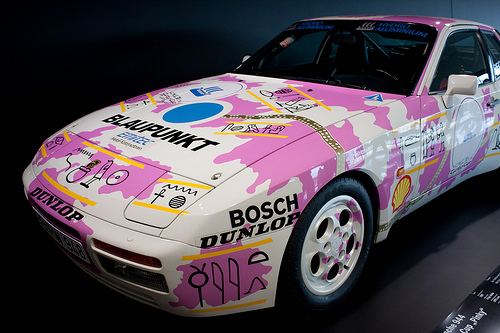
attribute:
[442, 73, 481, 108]
car mirror — white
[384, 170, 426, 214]
logo — Shell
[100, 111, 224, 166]
"blaupunkt" — black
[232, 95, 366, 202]
paint — Pink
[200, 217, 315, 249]
dunlop — black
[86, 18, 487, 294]
car — pink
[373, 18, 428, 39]
writing — blue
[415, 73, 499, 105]
mirror — white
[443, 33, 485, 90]
window — car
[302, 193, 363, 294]
hubcap — pink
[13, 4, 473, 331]
rim — white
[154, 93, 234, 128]
blue circle — large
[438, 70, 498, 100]
mirror — side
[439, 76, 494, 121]
mirror — white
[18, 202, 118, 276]
plate — white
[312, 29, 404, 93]
screen — clear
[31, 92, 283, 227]
symbols — stick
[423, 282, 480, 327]
strip — black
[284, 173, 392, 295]
tire — black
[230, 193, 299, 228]
bosch — black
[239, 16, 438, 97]
screen — tinted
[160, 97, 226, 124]
circle — blue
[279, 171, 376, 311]
wheel — black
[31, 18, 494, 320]
race car — white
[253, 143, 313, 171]
paint — pink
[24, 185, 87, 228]
dunlop — black